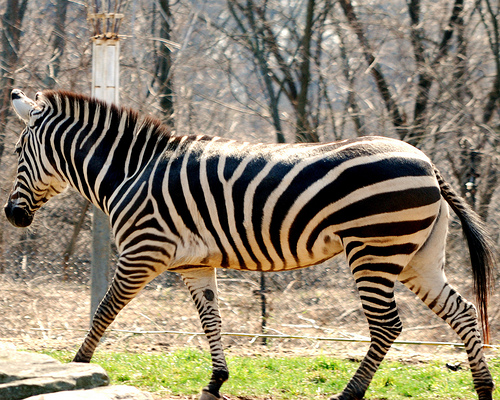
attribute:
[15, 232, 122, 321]
fencing — section, metal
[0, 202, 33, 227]
snout — black 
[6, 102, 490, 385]
stripe — Black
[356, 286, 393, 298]
stripe — black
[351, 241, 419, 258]
stripe — Black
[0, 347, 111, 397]
stone — gray, flat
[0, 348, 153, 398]
rock — flat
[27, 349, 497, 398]
grass — green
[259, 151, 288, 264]
stripe — black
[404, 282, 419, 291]
stripe — Black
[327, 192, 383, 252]
stripe — black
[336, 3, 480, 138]
trees — bare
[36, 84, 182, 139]
mane — black, white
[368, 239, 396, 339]
stripes — faded, black, dark stripes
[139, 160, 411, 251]
pattern — black and white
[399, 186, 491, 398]
leg — rear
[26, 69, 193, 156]
mane — zebra, black and white striped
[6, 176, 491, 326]
fence — chain link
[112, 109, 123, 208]
stripe — black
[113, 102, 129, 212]
stripe — black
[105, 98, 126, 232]
stripe — black